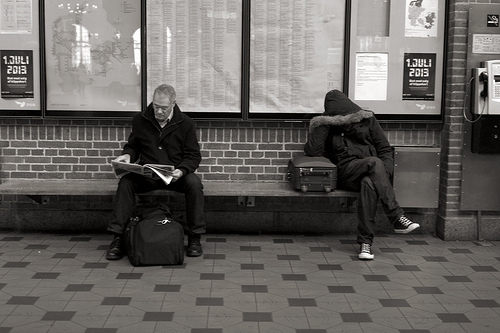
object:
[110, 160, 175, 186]
newspaper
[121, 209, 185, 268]
bag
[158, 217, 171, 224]
zipper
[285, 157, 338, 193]
suitcase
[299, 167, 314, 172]
zipper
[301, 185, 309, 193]
wheels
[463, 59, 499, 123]
phone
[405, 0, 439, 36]
map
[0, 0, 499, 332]
terminal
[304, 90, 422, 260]
person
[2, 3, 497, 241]
wall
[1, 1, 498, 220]
bricks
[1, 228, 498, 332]
tiles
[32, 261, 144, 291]
pattern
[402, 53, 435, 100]
poster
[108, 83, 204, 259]
man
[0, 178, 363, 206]
bench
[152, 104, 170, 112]
glasses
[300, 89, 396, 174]
jacket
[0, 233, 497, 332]
floor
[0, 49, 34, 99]
poster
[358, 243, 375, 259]
shoes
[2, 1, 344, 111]
window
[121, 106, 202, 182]
peacoat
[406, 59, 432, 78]
writing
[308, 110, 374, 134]
fur